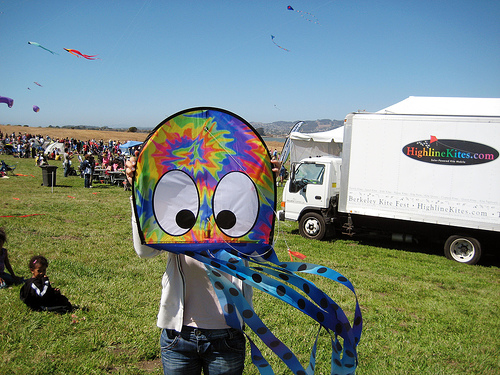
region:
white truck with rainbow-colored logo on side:
[277, 93, 497, 264]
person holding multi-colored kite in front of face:
[122, 106, 363, 372]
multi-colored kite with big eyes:
[126, 105, 360, 372]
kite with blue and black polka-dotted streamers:
[128, 106, 365, 371]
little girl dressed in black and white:
[19, 255, 74, 314]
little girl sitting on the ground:
[21, 252, 75, 318]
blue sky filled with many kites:
[0, 3, 324, 120]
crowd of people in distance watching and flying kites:
[4, 123, 134, 194]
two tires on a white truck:
[297, 205, 481, 266]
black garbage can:
[39, 163, 59, 189]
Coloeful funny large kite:
[132, 103, 282, 260]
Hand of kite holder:
[120, 155, 137, 192]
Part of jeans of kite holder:
[159, 334, 190, 364]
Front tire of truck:
[295, 208, 331, 238]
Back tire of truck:
[436, 229, 490, 268]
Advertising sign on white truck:
[398, 135, 498, 169]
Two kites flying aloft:
[21, 33, 97, 67]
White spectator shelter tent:
[288, 115, 343, 155]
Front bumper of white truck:
[276, 209, 286, 222]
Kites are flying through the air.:
[1, 3, 326, 114]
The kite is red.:
[61, 42, 97, 68]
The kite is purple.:
[0, 93, 16, 108]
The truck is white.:
[278, 110, 499, 264]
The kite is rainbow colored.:
[128, 105, 367, 373]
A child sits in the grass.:
[19, 256, 74, 313]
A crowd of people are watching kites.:
[0, 125, 140, 190]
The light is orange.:
[278, 198, 288, 207]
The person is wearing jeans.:
[157, 320, 247, 373]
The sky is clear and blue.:
[0, 0, 499, 130]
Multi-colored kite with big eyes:
[87, 101, 353, 311]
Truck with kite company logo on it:
[276, 56, 491, 278]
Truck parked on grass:
[273, 123, 495, 276]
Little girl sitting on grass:
[8, 220, 125, 355]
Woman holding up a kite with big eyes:
[118, 105, 333, 363]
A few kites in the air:
[9, 6, 363, 122]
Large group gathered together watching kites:
[3, 22, 133, 184]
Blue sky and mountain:
[256, 15, 353, 145]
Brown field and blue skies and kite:
[12, 6, 147, 139]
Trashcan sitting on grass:
[24, 155, 67, 211]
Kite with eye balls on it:
[96, 118, 310, 274]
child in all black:
[19, 269, 78, 323]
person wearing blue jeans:
[141, 310, 249, 367]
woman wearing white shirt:
[145, 259, 291, 344]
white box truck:
[321, 120, 467, 277]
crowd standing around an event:
[25, 123, 138, 198]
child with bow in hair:
[23, 249, 47, 270]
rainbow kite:
[94, 121, 284, 273]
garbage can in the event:
[29, 150, 85, 210]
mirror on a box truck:
[283, 148, 303, 205]